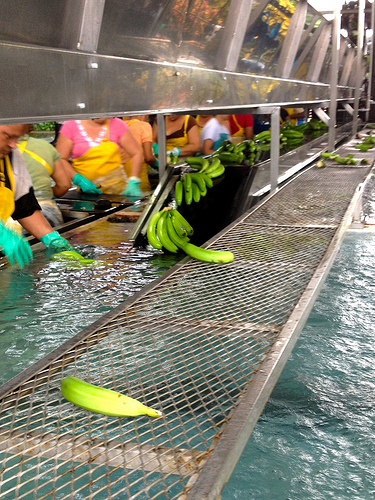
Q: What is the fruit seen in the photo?
A: Bananas.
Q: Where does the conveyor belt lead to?
A: The water.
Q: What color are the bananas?
A: Green.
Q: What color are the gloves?
A: Turquoise.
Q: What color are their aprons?
A: Yellow.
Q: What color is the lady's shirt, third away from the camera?
A: Pink.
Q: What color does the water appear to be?
A: Blue.